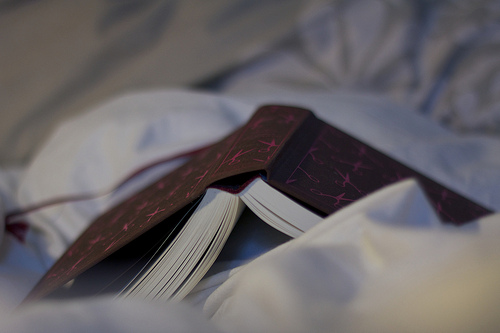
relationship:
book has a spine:
[12, 103, 496, 307] [205, 105, 314, 194]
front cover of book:
[16, 124, 245, 309] [12, 103, 496, 307]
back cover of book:
[268, 118, 497, 226] [12, 103, 496, 307]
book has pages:
[12, 103, 496, 307] [89, 177, 324, 308]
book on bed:
[12, 103, 496, 307] [0, 1, 498, 333]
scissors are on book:
[223, 148, 253, 167] [12, 103, 496, 307]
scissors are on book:
[258, 137, 280, 152] [12, 103, 496, 307]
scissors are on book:
[311, 187, 357, 208] [12, 103, 496, 307]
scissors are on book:
[333, 166, 366, 195] [12, 103, 496, 307]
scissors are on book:
[332, 154, 376, 177] [12, 103, 496, 307]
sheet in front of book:
[1, 180, 499, 333] [12, 103, 496, 307]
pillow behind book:
[17, 89, 499, 259] [12, 103, 496, 307]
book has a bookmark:
[12, 103, 496, 307] [4, 144, 213, 244]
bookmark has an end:
[4, 144, 213, 244] [4, 220, 30, 243]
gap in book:
[210, 170, 268, 191] [12, 103, 496, 307]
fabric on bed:
[1, 1, 499, 333] [0, 1, 498, 333]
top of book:
[16, 169, 329, 304] [12, 103, 496, 307]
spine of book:
[205, 105, 314, 194] [12, 103, 496, 307]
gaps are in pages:
[92, 192, 305, 302] [89, 177, 324, 308]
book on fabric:
[12, 103, 496, 307] [1, 1, 499, 333]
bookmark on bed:
[4, 144, 213, 244] [0, 1, 498, 333]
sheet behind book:
[0, 1, 499, 221] [12, 103, 496, 307]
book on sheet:
[12, 103, 496, 307] [1, 1, 499, 333]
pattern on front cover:
[14, 120, 247, 308] [16, 124, 245, 309]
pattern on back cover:
[271, 118, 496, 226] [268, 118, 497, 226]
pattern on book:
[18, 105, 496, 318] [12, 103, 496, 307]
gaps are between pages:
[92, 192, 305, 302] [89, 177, 324, 308]